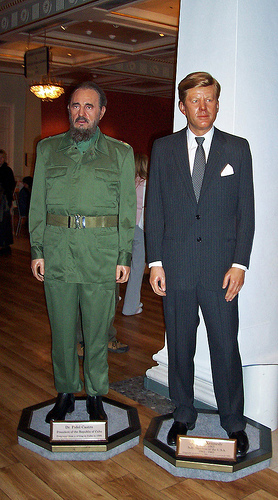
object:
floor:
[1, 273, 278, 500]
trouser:
[161, 291, 247, 434]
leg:
[198, 287, 248, 435]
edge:
[177, 434, 236, 445]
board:
[108, 444, 178, 492]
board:
[0, 461, 64, 499]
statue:
[143, 69, 257, 463]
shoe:
[165, 421, 189, 448]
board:
[247, 487, 278, 499]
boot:
[45, 392, 75, 424]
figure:
[28, 78, 138, 425]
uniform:
[28, 126, 138, 398]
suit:
[143, 131, 255, 434]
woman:
[120, 151, 152, 315]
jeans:
[120, 225, 144, 316]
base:
[15, 393, 144, 462]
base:
[143, 410, 274, 482]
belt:
[45, 211, 119, 227]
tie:
[190, 135, 208, 207]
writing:
[71, 425, 94, 430]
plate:
[51, 418, 109, 453]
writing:
[206, 440, 222, 446]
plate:
[175, 433, 237, 472]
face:
[183, 84, 217, 132]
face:
[68, 88, 101, 130]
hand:
[222, 267, 246, 304]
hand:
[149, 267, 169, 296]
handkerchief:
[219, 164, 235, 176]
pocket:
[219, 174, 237, 219]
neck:
[187, 124, 213, 137]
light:
[30, 81, 64, 102]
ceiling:
[0, 0, 183, 100]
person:
[0, 149, 16, 252]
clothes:
[0, 163, 17, 247]